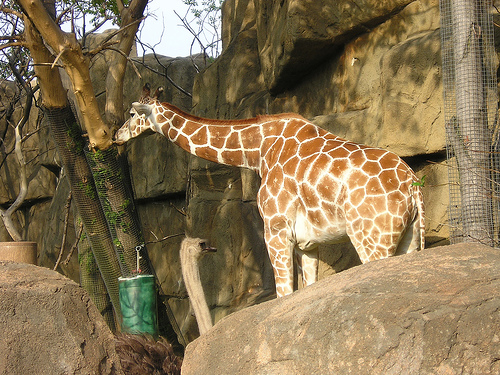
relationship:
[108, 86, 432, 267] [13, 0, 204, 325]
giraffe near tree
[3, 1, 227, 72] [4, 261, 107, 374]
sky above rock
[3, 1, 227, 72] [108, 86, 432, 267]
sky above giraffe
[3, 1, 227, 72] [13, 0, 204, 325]
sky above tree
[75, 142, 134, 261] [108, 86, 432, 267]
vines on giraffe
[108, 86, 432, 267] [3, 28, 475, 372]
giraffe in enclosure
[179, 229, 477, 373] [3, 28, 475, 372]
rock in enclosure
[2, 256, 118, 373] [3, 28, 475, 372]
rock in enclosure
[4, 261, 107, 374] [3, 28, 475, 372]
rock in enclosure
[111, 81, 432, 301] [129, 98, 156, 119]
giraffe has ear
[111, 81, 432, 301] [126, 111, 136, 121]
giraffe has eye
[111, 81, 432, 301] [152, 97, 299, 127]
giraffe has hair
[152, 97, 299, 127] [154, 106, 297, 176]
hair down neck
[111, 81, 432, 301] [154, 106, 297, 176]
giraffe has neck